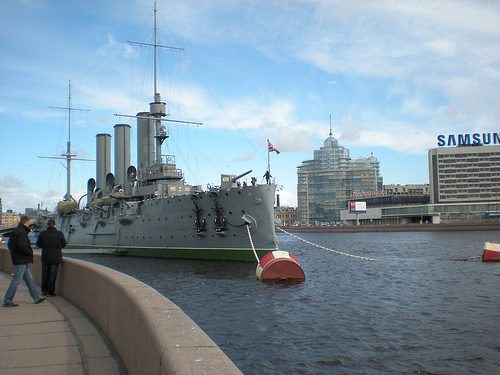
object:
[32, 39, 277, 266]
ship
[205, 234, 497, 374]
water.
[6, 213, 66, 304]
men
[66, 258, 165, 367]
wall.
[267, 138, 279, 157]
flag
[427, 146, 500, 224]
building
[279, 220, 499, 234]
waterfront.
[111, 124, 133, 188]
smokestack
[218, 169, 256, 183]
turret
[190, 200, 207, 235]
anchor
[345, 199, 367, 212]
sign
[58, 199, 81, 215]
lifeboats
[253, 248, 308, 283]
buoy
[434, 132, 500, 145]
sign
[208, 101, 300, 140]
cloud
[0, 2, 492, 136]
sky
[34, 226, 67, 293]
man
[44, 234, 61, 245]
black.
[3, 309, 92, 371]
sidewalk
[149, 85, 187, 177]
tower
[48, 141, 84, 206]
tower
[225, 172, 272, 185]
people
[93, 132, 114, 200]
smokestacks.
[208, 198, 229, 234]
anchor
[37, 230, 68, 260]
jacket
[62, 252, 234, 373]
ledge.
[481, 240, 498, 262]
anchor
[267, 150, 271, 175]
pole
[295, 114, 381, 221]
building